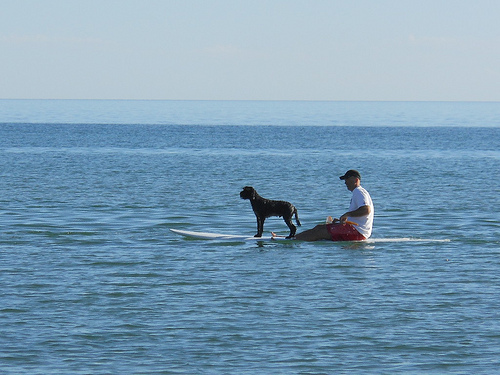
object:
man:
[281, 169, 374, 241]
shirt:
[342, 186, 375, 239]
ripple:
[48, 228, 103, 236]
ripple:
[111, 270, 164, 281]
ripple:
[375, 298, 450, 308]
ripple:
[195, 328, 244, 337]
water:
[0, 123, 500, 373]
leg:
[252, 212, 269, 236]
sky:
[1, 0, 499, 101]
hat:
[336, 169, 363, 181]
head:
[338, 167, 366, 190]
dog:
[237, 183, 302, 239]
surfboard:
[167, 222, 455, 250]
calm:
[0, 270, 500, 374]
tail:
[292, 209, 304, 227]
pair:
[324, 220, 367, 242]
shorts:
[326, 222, 367, 245]